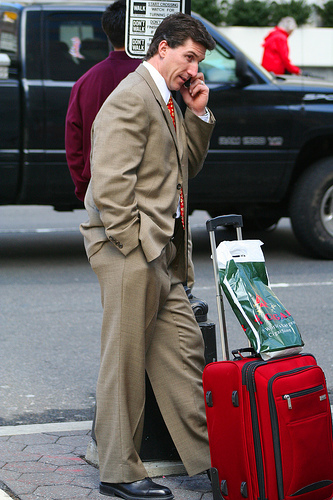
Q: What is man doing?
A: Talking.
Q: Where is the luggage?
A: By man.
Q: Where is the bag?
A: On luggage.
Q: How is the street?
A: Paved.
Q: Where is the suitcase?
A: On ground.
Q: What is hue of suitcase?
A: Red.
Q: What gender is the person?
A: Male.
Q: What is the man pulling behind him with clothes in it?
A: Suitcase.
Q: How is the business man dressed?
A: A suit.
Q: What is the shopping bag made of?
A: Plastic.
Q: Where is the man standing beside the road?
A: Sidewalk.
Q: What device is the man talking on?
A: Phone.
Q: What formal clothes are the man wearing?
A: Business suit.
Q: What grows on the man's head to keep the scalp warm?
A: Hair.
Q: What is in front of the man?
A: Rolling luggage.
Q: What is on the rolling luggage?
A: A plastic bag.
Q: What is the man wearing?
A: A tan suit.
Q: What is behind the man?
A: A dark truck.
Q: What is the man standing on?
A: A block of concrete.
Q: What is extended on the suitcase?
A: The handle.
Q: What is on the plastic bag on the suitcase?
A: Branding image.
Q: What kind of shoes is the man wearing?
A: Formal shoes.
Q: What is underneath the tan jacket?
A: A white shirt.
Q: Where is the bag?
A: On suitcase.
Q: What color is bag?
A: Green.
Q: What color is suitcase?
A: Red.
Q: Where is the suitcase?
A: Sidewalk.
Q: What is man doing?
A: Talking.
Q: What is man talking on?
A: Cellphone.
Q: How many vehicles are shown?
A: One.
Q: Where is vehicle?
A: On road.